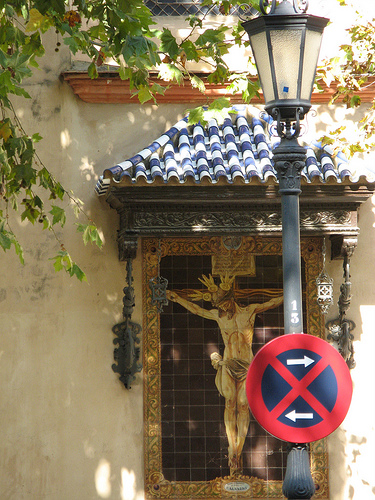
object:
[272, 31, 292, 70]
glass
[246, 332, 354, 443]
cross sign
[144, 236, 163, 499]
trimming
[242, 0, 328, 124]
lamp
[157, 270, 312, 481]
statue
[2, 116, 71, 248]
green leaves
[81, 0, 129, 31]
leaves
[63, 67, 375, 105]
board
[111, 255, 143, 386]
fixture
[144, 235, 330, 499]
sculpture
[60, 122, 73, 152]
light/building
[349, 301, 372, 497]
light/building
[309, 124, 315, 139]
reflection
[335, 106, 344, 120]
reflection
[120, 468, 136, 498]
reflection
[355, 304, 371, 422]
reflection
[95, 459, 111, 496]
reflection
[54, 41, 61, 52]
fruits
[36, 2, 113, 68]
branch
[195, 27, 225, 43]
leaves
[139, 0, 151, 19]
leaves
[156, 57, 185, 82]
leaves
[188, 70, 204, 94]
leaves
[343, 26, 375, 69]
leaves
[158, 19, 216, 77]
branch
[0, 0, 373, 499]
wall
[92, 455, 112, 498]
sunlight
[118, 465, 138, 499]
sunlight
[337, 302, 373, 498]
sunlight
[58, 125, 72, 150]
sunlight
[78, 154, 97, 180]
sunlight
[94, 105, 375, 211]
awning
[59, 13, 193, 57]
trees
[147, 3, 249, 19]
roof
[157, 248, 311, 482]
painting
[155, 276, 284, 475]
cross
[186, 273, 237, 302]
thorns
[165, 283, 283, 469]
jesus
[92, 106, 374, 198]
roof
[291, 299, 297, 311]
numbers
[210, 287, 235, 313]
head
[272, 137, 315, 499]
lamp pole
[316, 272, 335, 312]
light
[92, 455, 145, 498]
light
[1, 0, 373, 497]
building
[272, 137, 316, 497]
stand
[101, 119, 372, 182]
tiles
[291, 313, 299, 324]
number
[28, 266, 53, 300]
spots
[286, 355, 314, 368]
arrow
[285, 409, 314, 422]
arrow